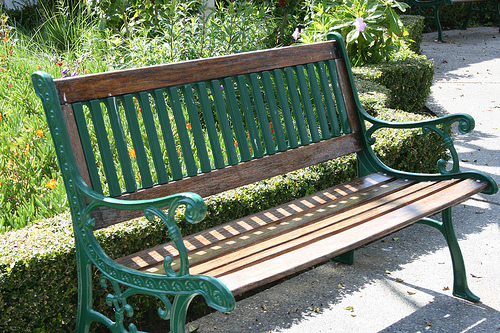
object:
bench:
[29, 32, 498, 332]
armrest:
[77, 182, 207, 223]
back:
[32, 33, 364, 228]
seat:
[113, 173, 487, 297]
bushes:
[0, 33, 211, 219]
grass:
[6, 89, 43, 217]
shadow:
[381, 277, 500, 332]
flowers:
[354, 19, 366, 31]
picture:
[0, 0, 499, 333]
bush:
[383, 53, 433, 110]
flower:
[45, 178, 58, 192]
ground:
[179, 27, 498, 332]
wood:
[56, 40, 337, 103]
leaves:
[338, 283, 343, 288]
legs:
[77, 263, 93, 333]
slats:
[149, 179, 414, 275]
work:
[30, 72, 89, 227]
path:
[418, 25, 500, 168]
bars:
[196, 82, 224, 168]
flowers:
[34, 130, 43, 137]